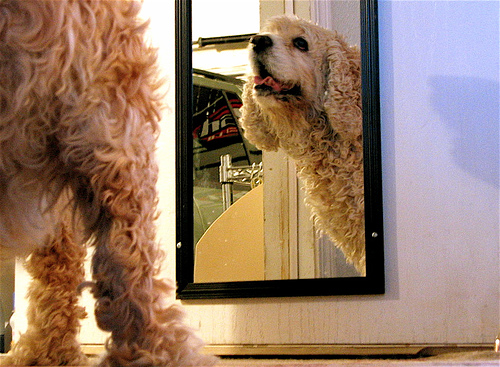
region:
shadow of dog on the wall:
[411, 62, 489, 121]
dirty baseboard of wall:
[253, 315, 497, 345]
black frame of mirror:
[158, 45, 434, 316]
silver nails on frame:
[366, 222, 382, 245]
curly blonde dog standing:
[13, 29, 168, 330]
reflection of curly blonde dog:
[243, 19, 353, 244]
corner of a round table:
[188, 197, 271, 265]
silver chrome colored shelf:
[221, 160, 247, 192]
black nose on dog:
[255, 31, 283, 72]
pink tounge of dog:
[259, 78, 319, 127]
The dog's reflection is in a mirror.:
[198, 2, 390, 276]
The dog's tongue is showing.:
[247, 65, 302, 100]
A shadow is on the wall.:
[407, 60, 498, 197]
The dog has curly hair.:
[295, 32, 368, 278]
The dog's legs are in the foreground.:
[0, 205, 208, 364]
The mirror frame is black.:
[162, 0, 399, 306]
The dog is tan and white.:
[1, 0, 172, 365]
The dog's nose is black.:
[239, 25, 286, 58]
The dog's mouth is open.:
[241, 57, 314, 107]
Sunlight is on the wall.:
[5, 195, 193, 346]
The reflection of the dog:
[236, 8, 366, 275]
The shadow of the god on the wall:
[422, 63, 499, 200]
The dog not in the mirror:
[0, 0, 226, 366]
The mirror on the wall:
[166, 1, 389, 302]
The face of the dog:
[238, 6, 318, 114]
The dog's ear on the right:
[324, 35, 368, 141]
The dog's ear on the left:
[239, 76, 280, 162]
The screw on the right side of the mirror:
[367, 226, 386, 249]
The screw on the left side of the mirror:
[173, 236, 187, 254]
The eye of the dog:
[286, 27, 315, 57]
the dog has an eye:
[282, 27, 320, 63]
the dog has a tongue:
[251, 67, 281, 92]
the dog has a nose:
[245, 25, 275, 58]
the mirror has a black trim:
[176, 277, 387, 300]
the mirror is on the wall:
[162, 15, 480, 305]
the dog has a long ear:
[324, 33, 358, 140]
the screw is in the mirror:
[362, 223, 378, 250]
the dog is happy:
[230, 0, 373, 268]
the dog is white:
[234, 7, 371, 266]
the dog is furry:
[245, 3, 370, 263]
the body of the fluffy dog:
[2, 0, 205, 364]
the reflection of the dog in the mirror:
[235, 8, 364, 270]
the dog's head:
[229, 17, 365, 147]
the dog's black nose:
[246, 30, 271, 56]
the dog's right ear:
[313, 32, 366, 140]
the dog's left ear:
[233, 70, 278, 155]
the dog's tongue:
[250, 67, 290, 94]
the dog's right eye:
[290, 31, 312, 60]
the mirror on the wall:
[163, 20, 391, 301]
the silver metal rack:
[211, 150, 273, 197]